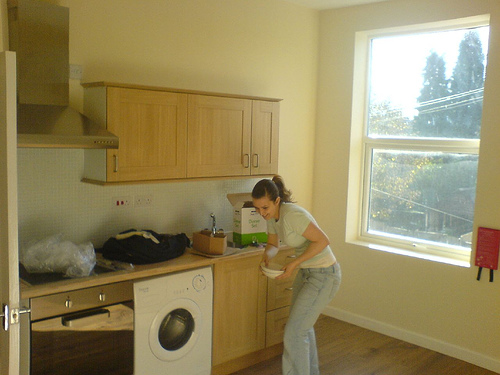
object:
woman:
[250, 174, 340, 374]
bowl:
[259, 261, 284, 279]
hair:
[251, 174, 297, 203]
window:
[344, 12, 489, 268]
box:
[227, 192, 267, 247]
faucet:
[211, 212, 217, 237]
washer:
[133, 266, 211, 374]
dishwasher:
[29, 279, 134, 374]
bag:
[20, 234, 97, 278]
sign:
[472, 227, 499, 282]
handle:
[113, 154, 118, 174]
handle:
[246, 155, 249, 167]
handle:
[253, 153, 259, 168]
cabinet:
[81, 81, 187, 187]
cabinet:
[188, 90, 251, 181]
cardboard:
[193, 230, 226, 256]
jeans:
[280, 260, 342, 374]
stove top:
[19, 260, 121, 287]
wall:
[317, 0, 499, 373]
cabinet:
[249, 96, 281, 177]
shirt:
[266, 202, 336, 268]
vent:
[7, 0, 120, 148]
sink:
[190, 238, 251, 259]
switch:
[114, 201, 127, 207]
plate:
[111, 196, 131, 207]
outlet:
[136, 197, 150, 204]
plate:
[133, 195, 151, 206]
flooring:
[223, 311, 498, 374]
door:
[0, 49, 21, 374]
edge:
[6, 50, 21, 373]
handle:
[0, 303, 10, 330]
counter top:
[20, 230, 294, 300]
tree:
[414, 50, 450, 135]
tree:
[450, 30, 484, 138]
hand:
[273, 266, 296, 284]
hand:
[259, 254, 266, 276]